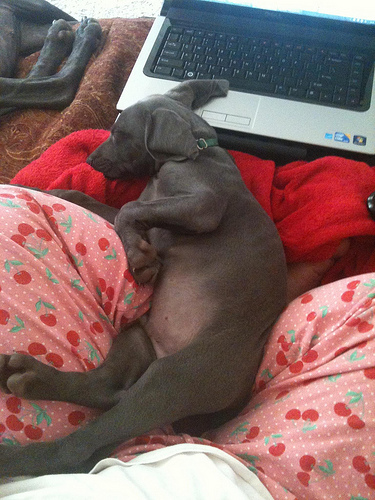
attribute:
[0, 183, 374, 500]
fabric — polka dotted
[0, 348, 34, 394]
foot of dog — exposed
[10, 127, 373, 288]
towel — crumpled, pink, red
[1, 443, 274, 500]
sheet — white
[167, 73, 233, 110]
ear — floppy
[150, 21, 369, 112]
keboard — normal sized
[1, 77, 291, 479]
dog — brown, asleep, sleeping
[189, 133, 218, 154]
colar — green, blue, dark green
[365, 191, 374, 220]
mouse — black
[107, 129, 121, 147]
dog's eyes — closed